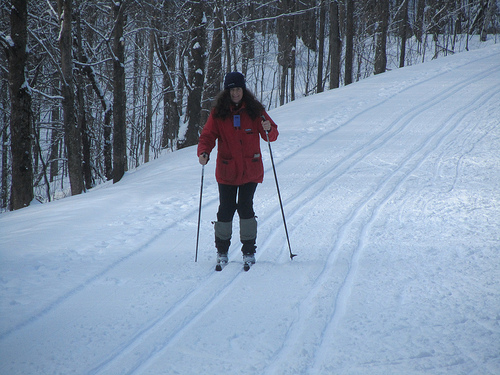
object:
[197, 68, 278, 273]
woman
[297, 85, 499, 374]
ski tracks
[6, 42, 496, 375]
snow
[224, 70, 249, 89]
hat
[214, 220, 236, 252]
leg warmers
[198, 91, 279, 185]
red coat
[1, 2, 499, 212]
trees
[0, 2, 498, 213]
snow on them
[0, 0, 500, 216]
no leaves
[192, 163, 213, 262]
ski poles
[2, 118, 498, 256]
sun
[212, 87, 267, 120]
long hair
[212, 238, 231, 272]
boots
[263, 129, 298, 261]
ski pole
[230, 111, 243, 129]
blue tag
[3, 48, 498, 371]
trail